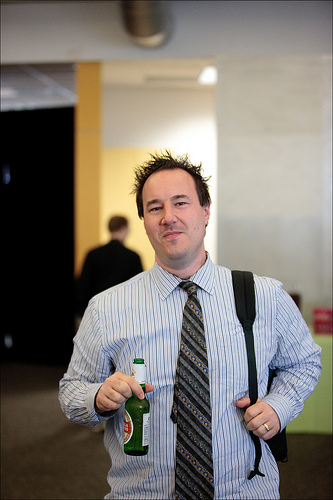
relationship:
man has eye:
[57, 151, 322, 499] [147, 203, 165, 215]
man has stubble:
[57, 151, 322, 499] [154, 224, 188, 237]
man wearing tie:
[57, 151, 322, 499] [169, 277, 220, 500]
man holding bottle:
[71, 211, 147, 328] [122, 355, 154, 463]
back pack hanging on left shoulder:
[226, 263, 295, 486] [211, 260, 298, 327]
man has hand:
[57, 151, 322, 499] [232, 390, 285, 446]